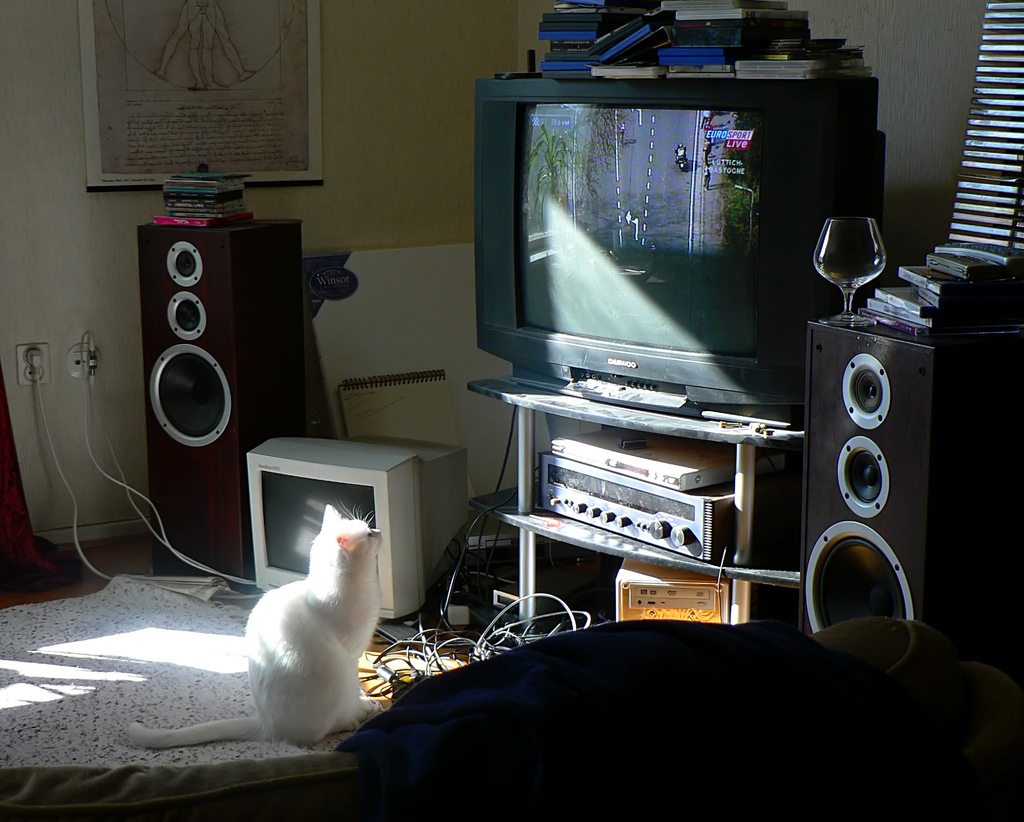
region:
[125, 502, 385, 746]
A fluffy white cat with a long tail.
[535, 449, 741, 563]
an old silver stereo receiver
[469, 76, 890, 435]
a large black TV showing the news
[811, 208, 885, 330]
an empty wine glass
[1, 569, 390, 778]
white rug with black spots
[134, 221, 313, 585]
large, brown, rectangular stereo speaker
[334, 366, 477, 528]
yellow spiral-bound legal pad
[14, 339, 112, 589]
long white power cable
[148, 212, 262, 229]
pink cd on top of speaker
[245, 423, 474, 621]
large white computer monitor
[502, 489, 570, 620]
A person eating a orange.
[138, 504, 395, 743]
White cat watching TV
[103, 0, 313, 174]
Poster of a Da Vinci drawing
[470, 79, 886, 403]
Old Panasonic color television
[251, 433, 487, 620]
Old white computer monitor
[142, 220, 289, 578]
Surround sound speaker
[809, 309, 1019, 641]
Surround sound speaker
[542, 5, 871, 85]
Collection of DVD and Blu-Ray Discs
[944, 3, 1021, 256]
Multiple music CDs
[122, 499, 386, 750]
white cat with pink ears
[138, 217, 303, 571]
black speaker with silver trim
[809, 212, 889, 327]
stemmed glassware sitting on a speaker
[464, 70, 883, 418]
black television on an entertainment stand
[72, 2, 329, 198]
picture hanging on the wall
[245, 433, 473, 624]
white monitor behind the cat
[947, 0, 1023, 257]
CDs in a CD rack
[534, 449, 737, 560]
stereo receiver in an entertainment center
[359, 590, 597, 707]
cables on the floor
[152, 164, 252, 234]
CDs sitting on the speaker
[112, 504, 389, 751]
White cat watching television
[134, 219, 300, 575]
Large box audio speaker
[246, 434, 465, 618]
Large old computer monitor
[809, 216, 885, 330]
Glass brandy snifter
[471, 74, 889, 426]
Old style television that is not a flat screen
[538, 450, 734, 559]
Old style radio receiver with knob controls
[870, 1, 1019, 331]
Stack of compact disks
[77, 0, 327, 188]
Poster art hanging on the wall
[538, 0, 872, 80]
Stack of DVDs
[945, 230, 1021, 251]
C.D. case on rack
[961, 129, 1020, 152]
C.D. case on rack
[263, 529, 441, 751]
a cat on the floor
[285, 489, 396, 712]
a white cat on the floor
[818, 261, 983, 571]
speaker on the floor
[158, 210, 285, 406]
speaker on the floor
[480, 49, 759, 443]
a tv on the floor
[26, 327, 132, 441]
a white cord on the floor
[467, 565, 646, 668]
a white cord on the floor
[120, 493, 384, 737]
cat is white and fluffy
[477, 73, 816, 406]
television is boxy and old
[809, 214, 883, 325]
glass is for drinking wine out of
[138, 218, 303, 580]
speaker is tall and brown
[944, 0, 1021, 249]
CDs are stacked up high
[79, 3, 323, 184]
this painting is on the wall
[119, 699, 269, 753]
the cat has a white long tail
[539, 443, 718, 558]
dvd player is black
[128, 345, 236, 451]
circle on a speaker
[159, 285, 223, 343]
circle on a speaker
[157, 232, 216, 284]
circle on a speaker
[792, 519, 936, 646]
circle on a speaker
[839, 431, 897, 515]
circle on a speaker